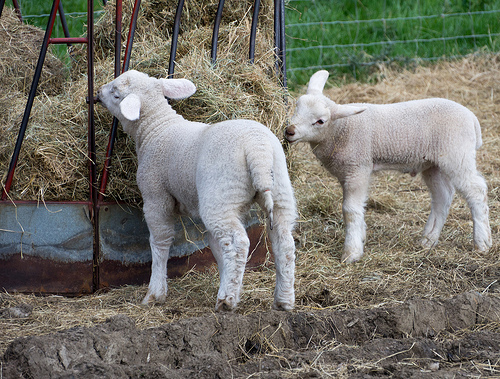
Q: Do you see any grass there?
A: Yes, there is grass.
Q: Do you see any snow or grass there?
A: Yes, there is grass.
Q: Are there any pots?
A: No, there are no pots.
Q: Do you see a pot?
A: No, there are no pots.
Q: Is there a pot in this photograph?
A: No, there are no pots.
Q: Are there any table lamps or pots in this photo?
A: No, there are no pots or table lamps.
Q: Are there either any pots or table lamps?
A: No, there are no pots or table lamps.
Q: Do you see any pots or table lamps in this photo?
A: No, there are no pots or table lamps.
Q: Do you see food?
A: Yes, there is food.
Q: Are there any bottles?
A: No, there are no bottles.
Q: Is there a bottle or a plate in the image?
A: No, there are no bottles or plates.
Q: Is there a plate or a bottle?
A: No, there are no bottles or plates.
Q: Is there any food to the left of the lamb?
A: Yes, there is food to the left of the lamb.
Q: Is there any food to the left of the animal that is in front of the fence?
A: Yes, there is food to the left of the lamb.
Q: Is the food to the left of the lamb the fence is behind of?
A: Yes, the food is to the left of the lamb.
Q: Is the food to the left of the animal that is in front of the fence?
A: Yes, the food is to the left of the lamb.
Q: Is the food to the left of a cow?
A: No, the food is to the left of the lamb.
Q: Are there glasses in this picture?
A: No, there are no glasses.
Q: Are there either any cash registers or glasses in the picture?
A: No, there are no glasses or cash registers.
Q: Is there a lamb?
A: Yes, there is a lamb.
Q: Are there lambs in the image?
A: Yes, there is a lamb.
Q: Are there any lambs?
A: Yes, there is a lamb.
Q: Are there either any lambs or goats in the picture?
A: Yes, there is a lamb.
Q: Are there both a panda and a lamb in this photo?
A: No, there is a lamb but no pandas.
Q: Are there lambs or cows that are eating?
A: Yes, the lamb is eating.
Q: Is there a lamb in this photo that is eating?
A: Yes, there is a lamb that is eating.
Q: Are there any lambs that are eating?
A: Yes, there is a lamb that is eating.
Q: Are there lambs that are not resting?
A: Yes, there is a lamb that is eating.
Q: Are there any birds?
A: No, there are no birds.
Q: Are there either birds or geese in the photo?
A: No, there are no birds or geese.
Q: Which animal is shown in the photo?
A: The animal is a lamb.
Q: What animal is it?
A: The animal is a lamb.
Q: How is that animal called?
A: This is a lamb.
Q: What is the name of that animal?
A: This is a lamb.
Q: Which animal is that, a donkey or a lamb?
A: This is a lamb.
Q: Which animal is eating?
A: The animal is a lamb.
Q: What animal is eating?
A: The animal is a lamb.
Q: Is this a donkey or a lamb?
A: This is a lamb.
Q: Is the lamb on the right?
A: Yes, the lamb is on the right of the image.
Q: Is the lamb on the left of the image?
A: No, the lamb is on the right of the image.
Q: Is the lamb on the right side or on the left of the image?
A: The lamb is on the right of the image.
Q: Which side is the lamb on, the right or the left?
A: The lamb is on the right of the image.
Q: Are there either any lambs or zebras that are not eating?
A: No, there is a lamb but it is eating.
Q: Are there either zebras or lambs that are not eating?
A: No, there is a lamb but it is eating.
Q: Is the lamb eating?
A: Yes, the lamb is eating.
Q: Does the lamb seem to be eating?
A: Yes, the lamb is eating.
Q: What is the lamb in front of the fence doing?
A: The lamb is eating.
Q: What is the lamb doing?
A: The lamb is eating.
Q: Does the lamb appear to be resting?
A: No, the lamb is eating.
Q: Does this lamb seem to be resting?
A: No, the lamb is eating.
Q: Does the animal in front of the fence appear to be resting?
A: No, the lamb is eating.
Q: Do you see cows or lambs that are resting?
A: No, there is a lamb but it is eating.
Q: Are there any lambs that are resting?
A: No, there is a lamb but it is eating.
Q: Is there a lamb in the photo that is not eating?
A: No, there is a lamb but it is eating.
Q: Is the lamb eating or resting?
A: The lamb is eating.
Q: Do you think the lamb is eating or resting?
A: The lamb is eating.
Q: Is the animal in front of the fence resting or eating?
A: The lamb is eating.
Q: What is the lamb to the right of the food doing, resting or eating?
A: The lamb is eating.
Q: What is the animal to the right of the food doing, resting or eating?
A: The lamb is eating.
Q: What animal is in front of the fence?
A: The lamb is in front of the fence.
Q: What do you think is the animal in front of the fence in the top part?
A: The animal is a lamb.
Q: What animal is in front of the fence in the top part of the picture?
A: The animal is a lamb.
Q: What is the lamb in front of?
A: The lamb is in front of the fence.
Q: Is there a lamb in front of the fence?
A: Yes, there is a lamb in front of the fence.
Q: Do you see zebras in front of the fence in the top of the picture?
A: No, there is a lamb in front of the fence.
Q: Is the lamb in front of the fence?
A: Yes, the lamb is in front of the fence.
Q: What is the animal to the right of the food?
A: The animal is a lamb.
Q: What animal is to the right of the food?
A: The animal is a lamb.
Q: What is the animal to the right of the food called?
A: The animal is a lamb.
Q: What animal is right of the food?
A: The animal is a lamb.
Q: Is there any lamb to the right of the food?
A: Yes, there is a lamb to the right of the food.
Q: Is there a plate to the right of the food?
A: No, there is a lamb to the right of the food.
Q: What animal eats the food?
A: The lamb eats the food.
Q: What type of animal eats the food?
A: The animal is a lamb.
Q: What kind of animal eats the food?
A: The animal is a lamb.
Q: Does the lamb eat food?
A: Yes, the lamb eats food.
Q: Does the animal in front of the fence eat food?
A: Yes, the lamb eats food.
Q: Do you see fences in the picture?
A: Yes, there is a fence.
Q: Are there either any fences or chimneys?
A: Yes, there is a fence.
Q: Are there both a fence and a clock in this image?
A: No, there is a fence but no clocks.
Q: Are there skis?
A: No, there are no skis.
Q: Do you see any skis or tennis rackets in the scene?
A: No, there are no skis or tennis rackets.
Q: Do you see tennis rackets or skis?
A: No, there are no skis or tennis rackets.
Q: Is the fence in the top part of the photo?
A: Yes, the fence is in the top of the image.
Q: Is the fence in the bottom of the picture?
A: No, the fence is in the top of the image.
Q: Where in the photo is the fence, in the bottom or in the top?
A: The fence is in the top of the image.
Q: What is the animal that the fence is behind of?
A: The animal is a lamb.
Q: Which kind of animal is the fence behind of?
A: The fence is behind the lamb.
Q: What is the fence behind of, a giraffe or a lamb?
A: The fence is behind a lamb.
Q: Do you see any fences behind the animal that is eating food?
A: Yes, there is a fence behind the lamb.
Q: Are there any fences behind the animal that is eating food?
A: Yes, there is a fence behind the lamb.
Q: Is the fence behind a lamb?
A: Yes, the fence is behind a lamb.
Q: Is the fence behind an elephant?
A: No, the fence is behind a lamb.